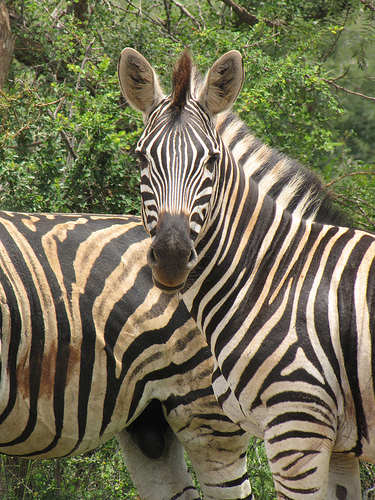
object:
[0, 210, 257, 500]
zebra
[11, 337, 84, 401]
dirt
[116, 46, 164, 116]
ear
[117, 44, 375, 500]
zebra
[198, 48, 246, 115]
ear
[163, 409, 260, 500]
leg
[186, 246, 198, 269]
nostril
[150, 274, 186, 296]
mouth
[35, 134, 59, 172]
leaves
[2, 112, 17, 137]
leaves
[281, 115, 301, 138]
leaves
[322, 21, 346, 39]
leaves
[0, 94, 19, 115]
leaves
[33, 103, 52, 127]
leaves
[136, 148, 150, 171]
eye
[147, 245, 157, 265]
nostril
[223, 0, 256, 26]
tree branch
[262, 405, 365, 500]
legs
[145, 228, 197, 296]
muzzle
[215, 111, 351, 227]
mane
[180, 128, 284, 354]
neck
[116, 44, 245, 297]
head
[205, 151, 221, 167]
eye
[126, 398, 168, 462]
testicles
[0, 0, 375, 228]
vegatation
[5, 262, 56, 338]
spot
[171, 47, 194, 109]
hair